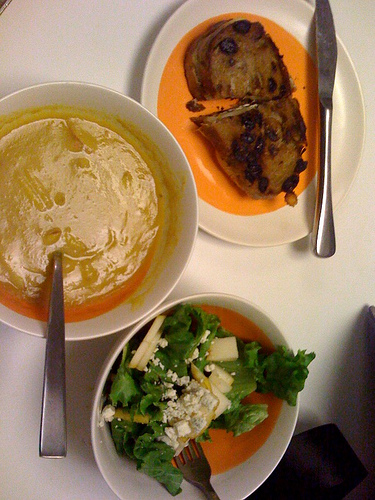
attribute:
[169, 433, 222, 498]
fork — silver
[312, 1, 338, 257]
knife — silver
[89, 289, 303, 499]
bowl — white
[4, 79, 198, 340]
dish — Orange dish, White edge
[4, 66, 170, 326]
soup — golden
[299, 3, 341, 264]
butterknife — silver, for butter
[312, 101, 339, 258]
handle — knife's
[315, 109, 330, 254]
glare — light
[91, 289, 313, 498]
white bowl — Orange inside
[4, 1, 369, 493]
table — white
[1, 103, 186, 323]
soup — creamy, yellow, orange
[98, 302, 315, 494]
salad — Dark green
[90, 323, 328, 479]
vegetable — green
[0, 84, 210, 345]
bowl — white, orange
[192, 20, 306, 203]
bread — brown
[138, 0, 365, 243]
plate — orange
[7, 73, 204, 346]
bowl — white, round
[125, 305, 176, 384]
tofu — white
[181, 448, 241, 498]
fork — silver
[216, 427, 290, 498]
white bowl — small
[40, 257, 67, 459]
handle — of silverware 